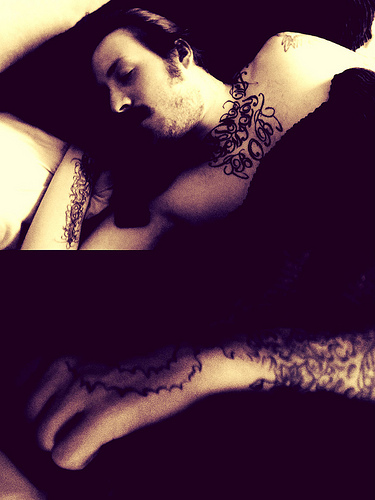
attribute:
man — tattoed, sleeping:
[30, 10, 371, 224]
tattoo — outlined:
[213, 90, 280, 180]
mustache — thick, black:
[117, 105, 157, 129]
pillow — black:
[37, 47, 90, 124]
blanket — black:
[276, 145, 373, 245]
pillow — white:
[1, 126, 43, 205]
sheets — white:
[28, 135, 52, 173]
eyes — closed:
[104, 64, 138, 100]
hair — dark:
[126, 4, 177, 51]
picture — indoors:
[1, 6, 374, 498]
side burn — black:
[158, 62, 185, 82]